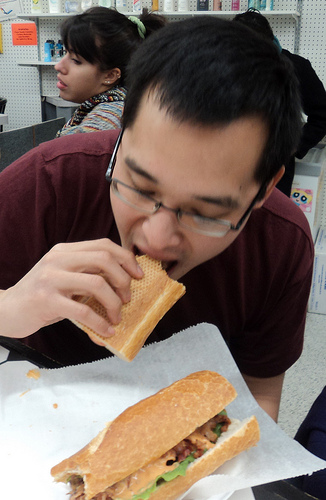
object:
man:
[0, 17, 315, 425]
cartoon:
[287, 185, 313, 213]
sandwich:
[63, 252, 187, 364]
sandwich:
[47, 369, 263, 499]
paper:
[0, 321, 324, 499]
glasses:
[104, 126, 272, 242]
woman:
[53, 3, 171, 139]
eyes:
[58, 50, 84, 68]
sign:
[11, 19, 39, 46]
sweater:
[57, 84, 127, 139]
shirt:
[0, 129, 313, 381]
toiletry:
[44, 37, 56, 65]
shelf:
[12, 56, 61, 73]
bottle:
[266, 0, 276, 13]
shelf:
[15, 8, 303, 23]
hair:
[57, 5, 167, 90]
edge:
[0, 330, 224, 381]